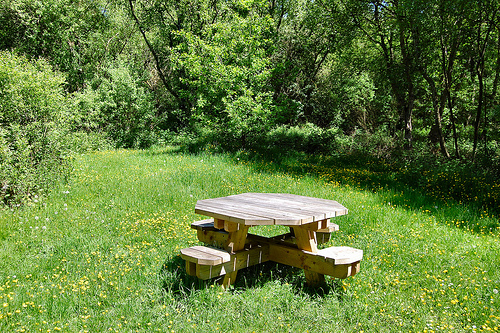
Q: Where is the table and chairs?
A: Field.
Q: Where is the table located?
A: On the grass.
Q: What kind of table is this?
A: Picnic.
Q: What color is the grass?
A: Green.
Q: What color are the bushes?
A: Green.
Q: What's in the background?
A: Trees.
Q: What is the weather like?
A: Sunny.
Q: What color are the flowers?
A: Yellow.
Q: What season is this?
A: Summer.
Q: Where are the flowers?
A: In the grass.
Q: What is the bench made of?
A: Wood.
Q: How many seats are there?
A: Four.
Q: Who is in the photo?
A: Nobody.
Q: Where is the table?
A: In the yard.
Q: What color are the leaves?
A: Green.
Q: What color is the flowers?
A: Yellow.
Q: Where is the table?
A: In the grass.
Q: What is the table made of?
A: Wood.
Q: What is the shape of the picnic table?
A: Octagon.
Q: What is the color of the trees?
A: Green.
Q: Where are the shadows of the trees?
A: On the ground.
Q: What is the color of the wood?
A: Brown.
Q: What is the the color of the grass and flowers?
A: Green and yellow.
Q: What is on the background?
A: Trees and grasses.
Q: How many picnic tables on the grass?
A: One.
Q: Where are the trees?
A: In the forest.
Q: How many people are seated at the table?
A: None.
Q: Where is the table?
A: Outside on grass.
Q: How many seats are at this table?
A: Four.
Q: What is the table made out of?
A: Wood.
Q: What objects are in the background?
A: Bushes are trees.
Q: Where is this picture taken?
A: The park.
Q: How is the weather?
A: Sunny.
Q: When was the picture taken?
A: Daytime.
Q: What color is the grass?
A: Green.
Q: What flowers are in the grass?
A: Dandelions.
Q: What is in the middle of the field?
A: A picnic table.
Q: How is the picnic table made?
A: Of wood.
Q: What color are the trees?
A: Green.